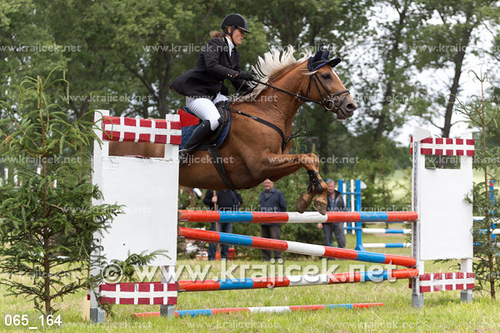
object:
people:
[201, 189, 243, 262]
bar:
[178, 209, 416, 223]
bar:
[177, 225, 417, 266]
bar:
[179, 266, 415, 292]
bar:
[130, 302, 384, 320]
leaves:
[137, 20, 144, 26]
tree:
[0, 65, 169, 320]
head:
[293, 49, 358, 120]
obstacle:
[174, 206, 417, 294]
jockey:
[171, 12, 253, 162]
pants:
[184, 90, 230, 130]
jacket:
[170, 31, 250, 96]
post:
[353, 180, 361, 246]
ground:
[16, 320, 267, 331]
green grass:
[405, 319, 413, 325]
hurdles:
[80, 13, 478, 327]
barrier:
[87, 107, 477, 315]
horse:
[108, 50, 356, 203]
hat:
[220, 13, 252, 35]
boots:
[177, 119, 215, 158]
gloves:
[238, 70, 254, 81]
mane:
[244, 46, 295, 94]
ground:
[423, 310, 500, 330]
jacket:
[259, 186, 287, 225]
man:
[254, 178, 289, 262]